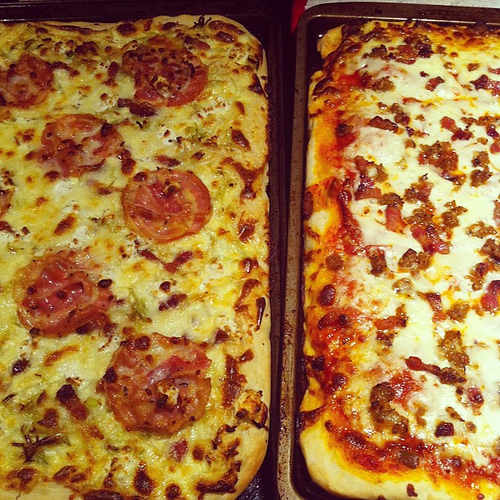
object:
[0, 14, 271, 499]
pizza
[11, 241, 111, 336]
toppings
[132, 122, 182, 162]
cheese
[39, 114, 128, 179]
pepperoni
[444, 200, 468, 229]
sausage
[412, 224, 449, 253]
ham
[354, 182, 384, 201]
bacon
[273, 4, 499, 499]
pan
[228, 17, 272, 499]
crust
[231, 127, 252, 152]
spot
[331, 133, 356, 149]
tomato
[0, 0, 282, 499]
left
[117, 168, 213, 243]
piece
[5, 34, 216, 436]
pieces